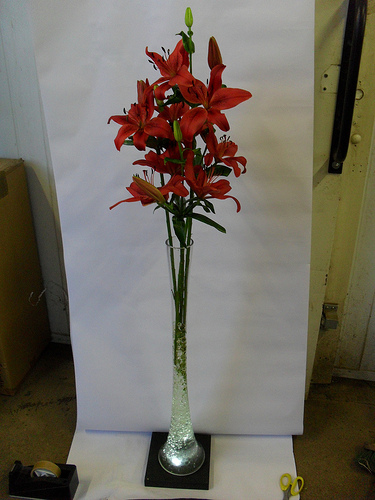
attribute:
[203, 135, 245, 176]
flower — red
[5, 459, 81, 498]
tape dispenser — black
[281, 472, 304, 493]
handle — yellow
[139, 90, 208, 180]
flower — red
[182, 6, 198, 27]
flower bud — unopened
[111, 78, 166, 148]
flower — red, tiger lily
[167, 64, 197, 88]
pedal — red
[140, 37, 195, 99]
flower — tall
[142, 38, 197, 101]
flower — red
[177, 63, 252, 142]
flower — red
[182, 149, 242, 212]
flower — red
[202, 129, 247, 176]
flower — red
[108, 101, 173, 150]
flower — red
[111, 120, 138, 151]
petal — red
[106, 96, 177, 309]
flower — tall